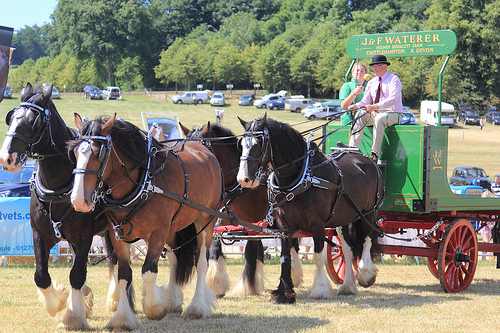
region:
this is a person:
[338, 39, 415, 166]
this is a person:
[332, 31, 364, 136]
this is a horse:
[213, 103, 422, 318]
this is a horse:
[167, 109, 305, 301]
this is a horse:
[65, 109, 218, 331]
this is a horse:
[1, 88, 129, 330]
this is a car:
[295, 93, 356, 133]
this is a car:
[235, 68, 287, 116]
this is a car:
[167, 62, 212, 112]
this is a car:
[57, 63, 107, 117]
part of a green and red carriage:
[330, 28, 499, 291]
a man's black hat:
[369, 53, 396, 68]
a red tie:
[373, 76, 383, 101]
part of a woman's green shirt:
[342, 79, 364, 123]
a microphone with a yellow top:
[359, 70, 371, 87]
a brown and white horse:
[237, 114, 387, 302]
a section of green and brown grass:
[0, 260, 489, 330]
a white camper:
[419, 93, 455, 127]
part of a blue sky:
[7, 0, 44, 20]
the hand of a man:
[360, 101, 373, 113]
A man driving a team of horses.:
[343, 53, 403, 160]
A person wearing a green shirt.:
[338, 63, 367, 121]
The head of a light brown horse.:
[68, 113, 120, 217]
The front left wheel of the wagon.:
[433, 217, 478, 298]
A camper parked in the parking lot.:
[416, 96, 458, 128]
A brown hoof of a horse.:
[272, 254, 299, 304]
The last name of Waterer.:
[383, 35, 439, 42]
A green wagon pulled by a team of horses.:
[315, 20, 498, 224]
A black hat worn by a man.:
[368, 53, 390, 70]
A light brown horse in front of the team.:
[68, 103, 223, 331]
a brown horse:
[166, 161, 226, 214]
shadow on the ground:
[207, 303, 262, 332]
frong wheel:
[437, 228, 482, 284]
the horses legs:
[27, 264, 99, 314]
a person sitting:
[366, 57, 406, 127]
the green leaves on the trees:
[185, 16, 271, 67]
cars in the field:
[167, 87, 267, 108]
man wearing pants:
[368, 120, 389, 150]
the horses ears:
[230, 115, 278, 130]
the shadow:
[385, 151, 415, 183]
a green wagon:
[328, 108, 498, 288]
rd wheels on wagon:
[324, 218, 482, 293]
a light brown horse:
[68, 108, 224, 320]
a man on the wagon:
[348, 51, 401, 163]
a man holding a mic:
[340, 63, 370, 115]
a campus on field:
[417, 91, 455, 128]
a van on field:
[172, 86, 208, 107]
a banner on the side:
[0, 191, 62, 260]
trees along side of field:
[0, 1, 497, 97]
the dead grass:
[0, 263, 499, 330]